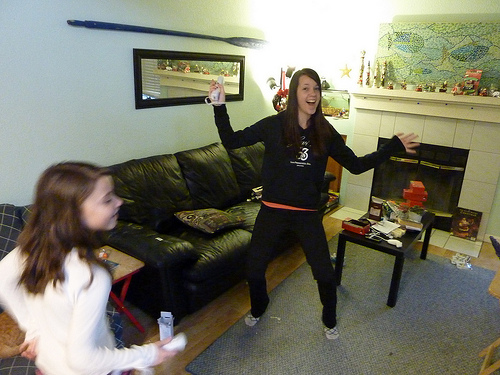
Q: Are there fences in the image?
A: No, there are no fences.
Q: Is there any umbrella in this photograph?
A: No, there are no umbrellas.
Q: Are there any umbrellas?
A: No, there are no umbrellas.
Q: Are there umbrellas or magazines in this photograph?
A: No, there are no umbrellas or magazines.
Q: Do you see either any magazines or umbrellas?
A: No, there are no umbrellas or magazines.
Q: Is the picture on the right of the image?
A: Yes, the picture is on the right of the image.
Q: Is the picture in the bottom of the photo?
A: No, the picture is in the top of the image.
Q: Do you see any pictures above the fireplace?
A: Yes, there is a picture above the fireplace.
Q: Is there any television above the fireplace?
A: No, there is a picture above the fireplace.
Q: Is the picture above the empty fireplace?
A: Yes, the picture is above the fire place.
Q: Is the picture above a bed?
A: No, the picture is above the fire place.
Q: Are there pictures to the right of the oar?
A: Yes, there is a picture to the right of the oar.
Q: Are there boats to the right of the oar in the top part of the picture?
A: No, there is a picture to the right of the paddle.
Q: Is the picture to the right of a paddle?
A: Yes, the picture is to the right of a paddle.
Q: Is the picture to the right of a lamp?
A: No, the picture is to the right of a paddle.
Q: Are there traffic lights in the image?
A: No, there are no traffic lights.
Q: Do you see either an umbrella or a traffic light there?
A: No, there are no traffic lights or umbrellas.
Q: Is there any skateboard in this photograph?
A: No, there are no skateboards.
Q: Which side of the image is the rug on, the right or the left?
A: The rug is on the right of the image.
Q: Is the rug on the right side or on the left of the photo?
A: The rug is on the right of the image.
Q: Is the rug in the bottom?
A: Yes, the rug is in the bottom of the image.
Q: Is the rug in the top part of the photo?
A: No, the rug is in the bottom of the image.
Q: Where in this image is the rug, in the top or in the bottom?
A: The rug is in the bottom of the image.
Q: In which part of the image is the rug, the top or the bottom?
A: The rug is in the bottom of the image.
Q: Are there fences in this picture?
A: No, there are no fences.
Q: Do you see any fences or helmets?
A: No, there are no fences or helmets.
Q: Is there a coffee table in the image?
A: Yes, there is a coffee table.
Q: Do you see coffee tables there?
A: Yes, there is a coffee table.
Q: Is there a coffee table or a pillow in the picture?
A: Yes, there is a coffee table.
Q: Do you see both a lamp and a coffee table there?
A: No, there is a coffee table but no lamps.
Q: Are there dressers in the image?
A: No, there are no dressers.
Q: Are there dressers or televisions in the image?
A: No, there are no dressers or televisions.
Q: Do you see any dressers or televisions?
A: No, there are no dressers or televisions.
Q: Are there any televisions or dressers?
A: No, there are no dressers or televisions.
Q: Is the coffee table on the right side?
A: Yes, the coffee table is on the right of the image.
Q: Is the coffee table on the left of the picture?
A: No, the coffee table is on the right of the image.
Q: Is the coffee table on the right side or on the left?
A: The coffee table is on the right of the image.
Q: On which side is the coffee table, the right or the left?
A: The coffee table is on the right of the image.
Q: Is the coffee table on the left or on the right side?
A: The coffee table is on the right of the image.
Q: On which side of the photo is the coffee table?
A: The coffee table is on the right of the image.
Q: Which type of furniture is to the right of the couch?
A: The piece of furniture is a coffee table.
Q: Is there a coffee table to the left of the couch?
A: No, the coffee table is to the right of the couch.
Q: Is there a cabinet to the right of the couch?
A: No, there is a coffee table to the right of the couch.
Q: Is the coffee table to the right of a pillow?
A: No, the coffee table is to the right of the couch.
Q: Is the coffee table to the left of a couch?
A: No, the coffee table is to the right of a couch.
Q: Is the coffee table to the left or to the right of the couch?
A: The coffee table is to the right of the couch.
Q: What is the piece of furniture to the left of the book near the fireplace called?
A: The piece of furniture is a coffee table.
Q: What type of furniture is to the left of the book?
A: The piece of furniture is a coffee table.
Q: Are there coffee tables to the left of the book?
A: Yes, there is a coffee table to the left of the book.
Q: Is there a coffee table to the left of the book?
A: Yes, there is a coffee table to the left of the book.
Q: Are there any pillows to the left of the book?
A: No, there is a coffee table to the left of the book.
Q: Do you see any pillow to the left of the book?
A: No, there is a coffee table to the left of the book.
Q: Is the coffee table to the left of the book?
A: Yes, the coffee table is to the left of the book.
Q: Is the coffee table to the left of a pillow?
A: No, the coffee table is to the left of the book.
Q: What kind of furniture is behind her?
A: The piece of furniture is a coffee table.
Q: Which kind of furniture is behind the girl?
A: The piece of furniture is a coffee table.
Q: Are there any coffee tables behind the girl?
A: Yes, there is a coffee table behind the girl.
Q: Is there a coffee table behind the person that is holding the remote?
A: Yes, there is a coffee table behind the girl.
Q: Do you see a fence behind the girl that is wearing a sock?
A: No, there is a coffee table behind the girl.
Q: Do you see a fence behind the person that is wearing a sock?
A: No, there is a coffee table behind the girl.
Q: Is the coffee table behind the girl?
A: Yes, the coffee table is behind the girl.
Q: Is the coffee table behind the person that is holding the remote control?
A: Yes, the coffee table is behind the girl.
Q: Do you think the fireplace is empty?
A: Yes, the fireplace is empty.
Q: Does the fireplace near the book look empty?
A: Yes, the fire place is empty.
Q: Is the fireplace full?
A: No, the fireplace is empty.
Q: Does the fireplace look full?
A: No, the fireplace is empty.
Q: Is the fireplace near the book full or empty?
A: The fire place is empty.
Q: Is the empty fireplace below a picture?
A: Yes, the fireplace is below a picture.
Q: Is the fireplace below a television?
A: No, the fireplace is below a picture.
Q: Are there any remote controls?
A: Yes, there is a remote control.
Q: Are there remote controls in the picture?
A: Yes, there is a remote control.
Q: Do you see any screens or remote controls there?
A: Yes, there is a remote control.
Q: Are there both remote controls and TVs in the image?
A: No, there is a remote control but no televisions.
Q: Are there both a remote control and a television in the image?
A: No, there is a remote control but no televisions.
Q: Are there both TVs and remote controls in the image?
A: No, there is a remote control but no televisions.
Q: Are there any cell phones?
A: No, there are no cell phones.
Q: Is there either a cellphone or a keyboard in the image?
A: No, there are no cell phones or keyboards.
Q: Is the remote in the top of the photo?
A: Yes, the remote is in the top of the image.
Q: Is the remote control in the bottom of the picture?
A: No, the remote control is in the top of the image.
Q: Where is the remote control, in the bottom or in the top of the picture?
A: The remote control is in the top of the image.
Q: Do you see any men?
A: No, there are no men.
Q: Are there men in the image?
A: No, there are no men.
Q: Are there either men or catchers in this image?
A: No, there are no men or catchers.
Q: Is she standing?
A: Yes, the girl is standing.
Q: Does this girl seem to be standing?
A: Yes, the girl is standing.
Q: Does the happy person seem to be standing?
A: Yes, the girl is standing.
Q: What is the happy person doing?
A: The girl is standing.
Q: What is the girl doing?
A: The girl is standing.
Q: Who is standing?
A: The girl is standing.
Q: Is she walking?
A: No, the girl is standing.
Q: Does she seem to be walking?
A: No, the girl is standing.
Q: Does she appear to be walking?
A: No, the girl is standing.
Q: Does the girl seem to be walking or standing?
A: The girl is standing.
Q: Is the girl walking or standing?
A: The girl is standing.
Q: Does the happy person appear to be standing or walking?
A: The girl is standing.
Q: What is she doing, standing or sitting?
A: The girl is standing.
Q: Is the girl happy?
A: Yes, the girl is happy.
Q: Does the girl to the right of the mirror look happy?
A: Yes, the girl is happy.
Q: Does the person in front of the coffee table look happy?
A: Yes, the girl is happy.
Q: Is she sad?
A: No, the girl is happy.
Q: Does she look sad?
A: No, the girl is happy.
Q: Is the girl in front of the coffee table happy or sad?
A: The girl is happy.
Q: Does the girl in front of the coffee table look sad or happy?
A: The girl is happy.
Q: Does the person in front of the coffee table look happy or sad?
A: The girl is happy.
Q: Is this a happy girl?
A: Yes, this is a happy girl.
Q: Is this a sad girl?
A: No, this is a happy girl.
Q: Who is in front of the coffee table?
A: The girl is in front of the coffee table.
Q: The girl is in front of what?
A: The girl is in front of the coffee table.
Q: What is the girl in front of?
A: The girl is in front of the coffee table.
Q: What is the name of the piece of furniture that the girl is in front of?
A: The piece of furniture is a coffee table.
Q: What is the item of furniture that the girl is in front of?
A: The piece of furniture is a coffee table.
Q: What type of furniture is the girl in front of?
A: The girl is in front of the coffee table.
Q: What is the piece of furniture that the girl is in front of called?
A: The piece of furniture is a coffee table.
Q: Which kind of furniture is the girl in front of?
A: The girl is in front of the coffee table.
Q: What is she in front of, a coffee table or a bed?
A: The girl is in front of a coffee table.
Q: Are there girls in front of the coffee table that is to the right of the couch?
A: Yes, there is a girl in front of the coffee table.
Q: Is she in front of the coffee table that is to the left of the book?
A: Yes, the girl is in front of the coffee table.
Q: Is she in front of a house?
A: No, the girl is in front of the coffee table.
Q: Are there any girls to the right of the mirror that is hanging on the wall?
A: Yes, there is a girl to the right of the mirror.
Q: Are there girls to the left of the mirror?
A: No, the girl is to the right of the mirror.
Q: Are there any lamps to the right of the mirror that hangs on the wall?
A: No, there is a girl to the right of the mirror.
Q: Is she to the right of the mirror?
A: Yes, the girl is to the right of the mirror.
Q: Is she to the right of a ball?
A: No, the girl is to the right of the mirror.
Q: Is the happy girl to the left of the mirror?
A: No, the girl is to the right of the mirror.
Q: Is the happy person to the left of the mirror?
A: No, the girl is to the right of the mirror.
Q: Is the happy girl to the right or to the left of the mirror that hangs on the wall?
A: The girl is to the right of the mirror.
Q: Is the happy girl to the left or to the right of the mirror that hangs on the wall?
A: The girl is to the right of the mirror.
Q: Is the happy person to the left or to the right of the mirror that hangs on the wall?
A: The girl is to the right of the mirror.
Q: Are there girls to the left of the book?
A: Yes, there is a girl to the left of the book.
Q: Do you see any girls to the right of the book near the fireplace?
A: No, the girl is to the left of the book.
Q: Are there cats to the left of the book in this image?
A: No, there is a girl to the left of the book.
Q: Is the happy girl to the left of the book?
A: Yes, the girl is to the left of the book.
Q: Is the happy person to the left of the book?
A: Yes, the girl is to the left of the book.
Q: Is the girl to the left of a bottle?
A: No, the girl is to the left of the book.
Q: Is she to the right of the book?
A: No, the girl is to the left of the book.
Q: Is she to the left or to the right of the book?
A: The girl is to the left of the book.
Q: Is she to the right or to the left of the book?
A: The girl is to the left of the book.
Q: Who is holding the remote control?
A: The girl is holding the remote control.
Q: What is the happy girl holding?
A: The girl is holding the remote.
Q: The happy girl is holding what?
A: The girl is holding the remote.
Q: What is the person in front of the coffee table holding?
A: The girl is holding the remote.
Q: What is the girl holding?
A: The girl is holding the remote.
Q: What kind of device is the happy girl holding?
A: The girl is holding the remote.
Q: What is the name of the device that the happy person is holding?
A: The device is a remote control.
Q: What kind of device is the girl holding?
A: The girl is holding the remote.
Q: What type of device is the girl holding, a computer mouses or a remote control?
A: The girl is holding a remote control.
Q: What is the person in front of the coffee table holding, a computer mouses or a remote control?
A: The girl is holding a remote control.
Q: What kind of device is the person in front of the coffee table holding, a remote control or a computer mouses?
A: The girl is holding a remote control.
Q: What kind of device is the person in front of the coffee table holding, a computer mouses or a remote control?
A: The girl is holding a remote control.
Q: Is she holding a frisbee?
A: No, the girl is holding the remote.